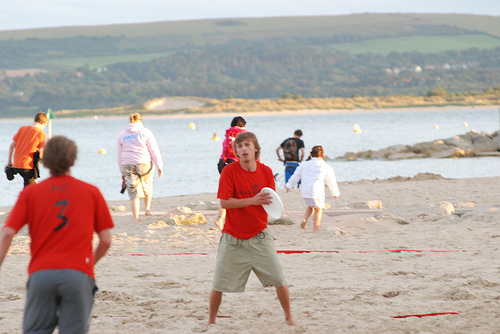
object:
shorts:
[121, 161, 156, 200]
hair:
[232, 131, 261, 160]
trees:
[0, 44, 500, 110]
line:
[129, 252, 208, 256]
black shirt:
[280, 137, 305, 162]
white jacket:
[285, 157, 341, 199]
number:
[51, 200, 69, 233]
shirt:
[2, 175, 114, 282]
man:
[0, 135, 115, 334]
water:
[0, 110, 499, 207]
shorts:
[211, 227, 288, 294]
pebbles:
[350, 199, 476, 216]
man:
[207, 132, 299, 328]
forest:
[0, 22, 500, 109]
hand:
[253, 192, 273, 205]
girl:
[284, 145, 341, 234]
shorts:
[20, 269, 99, 334]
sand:
[0, 177, 497, 334]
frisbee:
[259, 187, 284, 220]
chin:
[241, 156, 250, 161]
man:
[4, 112, 50, 190]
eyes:
[238, 144, 250, 148]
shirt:
[217, 160, 276, 240]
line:
[389, 312, 461, 320]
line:
[275, 249, 480, 255]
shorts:
[284, 162, 301, 185]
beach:
[1, 104, 500, 334]